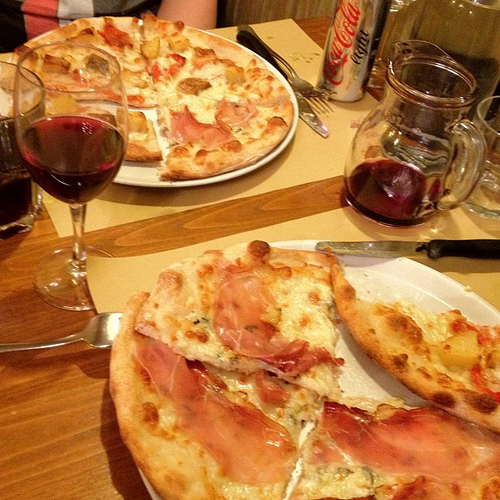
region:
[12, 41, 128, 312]
wine in a stem glass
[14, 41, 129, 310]
a glass of red wine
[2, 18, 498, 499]
two pizzas on white plates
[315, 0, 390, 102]
a Coca Cola light can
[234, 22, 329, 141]
a knife and fork on the table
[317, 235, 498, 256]
a black handle knife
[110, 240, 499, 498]
three whole slices of pizza on the plate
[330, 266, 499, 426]
a piece of an eaten pizza slice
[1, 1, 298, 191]
a plate of pizza on the table in front of a woman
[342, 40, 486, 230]
a glass pitcher containing a small amount of wine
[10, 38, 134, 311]
clear wine glass on long stem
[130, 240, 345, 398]
slice of pizza on bottom plate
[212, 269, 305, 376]
partial slice of canadian bacon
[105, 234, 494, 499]
round white ceramic plate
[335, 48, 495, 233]
clear glass drinking mug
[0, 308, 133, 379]
silver tone dinner fork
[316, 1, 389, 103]
silver and red can of coca-cola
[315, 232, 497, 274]
black and silver knife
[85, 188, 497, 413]
brown paper place mat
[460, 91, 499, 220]
empty clear drinking glass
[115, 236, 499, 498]
a full pizza pie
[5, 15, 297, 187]
a full pizza pie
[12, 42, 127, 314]
a tall stemmed glass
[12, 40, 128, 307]
a clear glass of red wine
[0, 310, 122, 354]
a silver fork utensil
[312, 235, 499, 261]
a black handled knife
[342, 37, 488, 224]
a glass syrup jar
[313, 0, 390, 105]
a silver can of Coca-Cola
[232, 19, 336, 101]
a silver fork utensil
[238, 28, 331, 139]
a black handled knife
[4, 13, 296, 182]
a pizza on a white plate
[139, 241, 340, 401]
a slice of cheese and ham pizza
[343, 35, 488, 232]
a glass pitcher of wine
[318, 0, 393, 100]
a can of soda on a table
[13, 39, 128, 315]
a glass of wine on a table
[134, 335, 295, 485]
a slice of ham on a pizza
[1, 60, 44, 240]
a glass filled with wine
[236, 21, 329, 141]
utensils on a paper mat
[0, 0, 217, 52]
person sitting in front of a pizza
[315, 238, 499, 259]
a knife propped on a white plate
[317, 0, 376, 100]
A silver can of Coca-Cola Light.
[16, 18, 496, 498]
Two pizzas.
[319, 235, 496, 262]
A black handled knife.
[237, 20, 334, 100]
A silver fork.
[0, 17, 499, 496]
A wooden table.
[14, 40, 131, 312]
A wine glass.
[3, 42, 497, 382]
Beige placemats.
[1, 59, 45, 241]
A small glass cup.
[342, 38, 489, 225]
A glass mug with a handle on it.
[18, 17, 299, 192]
A round white plate.